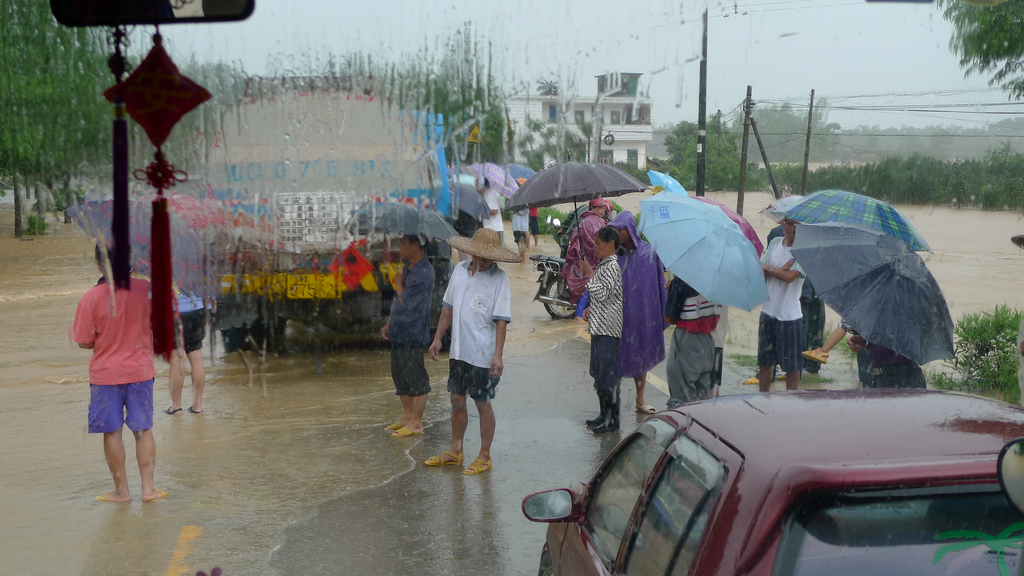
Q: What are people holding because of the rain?
A: Umbrellas.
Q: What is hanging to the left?
A: A tassel.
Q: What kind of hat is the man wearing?
A: Straw.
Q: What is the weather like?
A: Rainy.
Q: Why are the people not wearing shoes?
A: The people are barefoot.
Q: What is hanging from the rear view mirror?
A: Decorations.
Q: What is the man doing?
A: Standing in the rain.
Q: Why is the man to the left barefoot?
A: So the man's shoes don't get wet.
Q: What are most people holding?
A: Umbrellas.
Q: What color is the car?
A: Red.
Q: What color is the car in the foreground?
A: Red.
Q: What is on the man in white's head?
A: A hat.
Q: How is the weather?
A: Rainy.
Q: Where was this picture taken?
A: A market.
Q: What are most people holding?
A: Umbrellas.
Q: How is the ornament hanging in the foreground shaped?
A: Like a top.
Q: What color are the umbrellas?
A: Blue and black.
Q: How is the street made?
A: Of concrete.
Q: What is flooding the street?
A: Water.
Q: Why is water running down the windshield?
A: It's raining.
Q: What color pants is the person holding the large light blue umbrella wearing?
A: Gray.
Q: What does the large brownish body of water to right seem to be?
A: An overflowing river.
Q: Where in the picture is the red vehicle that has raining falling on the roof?
A: On the bottom right corner.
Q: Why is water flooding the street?
A: The river overflowed.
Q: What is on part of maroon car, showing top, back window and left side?
A: Palm tree sticker.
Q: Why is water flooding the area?
A: The river over flowed.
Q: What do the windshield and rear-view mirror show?
A: Rain splatters and ornaments.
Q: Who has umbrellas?
A: Numerous pedestrians.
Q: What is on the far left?
A: Green trees in the distance.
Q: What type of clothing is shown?
A: Short and other leg-revealing types.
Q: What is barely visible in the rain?
A: A blue bus.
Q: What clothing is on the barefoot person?
A: Purple shorts and a pink shirt.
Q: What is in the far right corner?
A: A burgundy vehicle.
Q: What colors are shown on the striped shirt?
A: Black and white.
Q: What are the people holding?
A: Umbrellas.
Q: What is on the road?
A: Water.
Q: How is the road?
A: Flooded with water.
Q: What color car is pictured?
A: Maroon.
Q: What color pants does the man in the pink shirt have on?
A: Purple.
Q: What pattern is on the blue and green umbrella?
A: Plaid.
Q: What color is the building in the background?
A: White.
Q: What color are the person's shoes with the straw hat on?
A: Yellow.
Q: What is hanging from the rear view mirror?
A: Decorations with tassels.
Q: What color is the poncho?
A: Purple.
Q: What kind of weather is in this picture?
A: Rainy.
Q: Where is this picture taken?
A: In a car.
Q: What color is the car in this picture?
A: Burgundy.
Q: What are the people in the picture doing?
A: Standing.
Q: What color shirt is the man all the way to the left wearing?
A: Pink.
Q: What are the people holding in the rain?
A: Umbrellas.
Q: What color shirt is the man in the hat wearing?
A: White.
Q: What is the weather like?
A: Raining.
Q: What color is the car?
A: Red.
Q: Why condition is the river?
A: Muddy.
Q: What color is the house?
A: White.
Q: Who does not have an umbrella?
A: A woman.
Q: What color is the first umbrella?
A: Blue.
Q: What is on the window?
A: Rain.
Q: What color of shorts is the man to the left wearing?
A: Purple.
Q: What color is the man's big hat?
A: Brown.